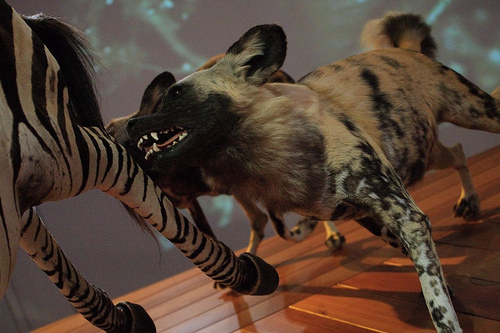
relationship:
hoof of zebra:
[233, 228, 294, 308] [8, 18, 139, 247]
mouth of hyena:
[109, 13, 297, 237] [92, 6, 485, 299]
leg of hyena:
[90, 141, 193, 245] [202, 38, 422, 218]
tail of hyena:
[379, 13, 430, 44] [202, 38, 422, 218]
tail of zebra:
[63, 35, 116, 103] [8, 18, 139, 247]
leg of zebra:
[90, 141, 193, 245] [8, 18, 139, 247]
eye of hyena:
[171, 82, 201, 100] [202, 38, 422, 218]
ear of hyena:
[247, 24, 304, 78] [202, 38, 422, 218]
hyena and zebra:
[202, 38, 422, 218] [8, 18, 139, 247]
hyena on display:
[202, 38, 422, 218] [131, 23, 410, 247]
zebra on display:
[8, 18, 139, 247] [92, 6, 485, 299]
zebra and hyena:
[8, 18, 139, 247] [202, 38, 422, 218]